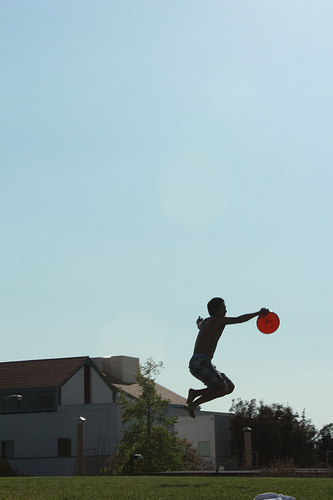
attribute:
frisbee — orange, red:
[256, 311, 280, 334]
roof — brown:
[1, 356, 201, 409]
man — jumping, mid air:
[184, 296, 269, 416]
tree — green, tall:
[100, 358, 191, 473]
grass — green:
[1, 477, 333, 499]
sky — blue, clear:
[0, 0, 332, 447]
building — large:
[0, 355, 235, 475]